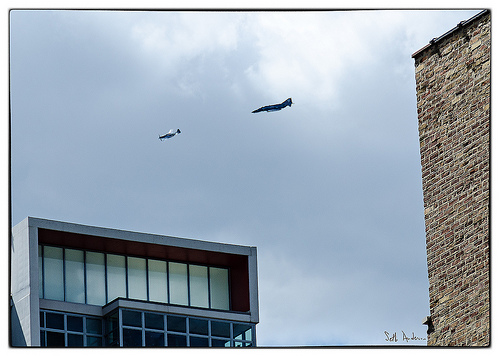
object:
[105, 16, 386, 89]
cloud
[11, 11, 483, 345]
sky